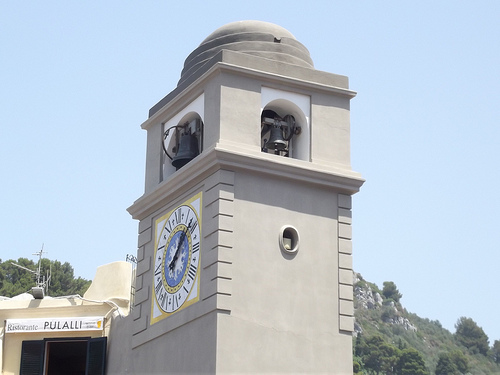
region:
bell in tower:
[267, 119, 289, 150]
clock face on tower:
[152, 201, 197, 315]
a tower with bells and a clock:
[128, 17, 365, 372]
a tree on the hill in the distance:
[452, 317, 490, 349]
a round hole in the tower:
[276, 222, 301, 257]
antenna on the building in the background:
[12, 246, 60, 293]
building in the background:
[1, 258, 132, 373]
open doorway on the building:
[44, 339, 88, 374]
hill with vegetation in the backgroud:
[352, 264, 497, 374]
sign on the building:
[4, 319, 104, 331]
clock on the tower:
[148, 212, 202, 312]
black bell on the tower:
[256, 100, 304, 162]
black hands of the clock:
[173, 216, 185, 259]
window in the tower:
[275, 219, 307, 259]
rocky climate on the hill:
[359, 277, 384, 316]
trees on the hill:
[358, 330, 423, 372]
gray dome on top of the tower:
[170, 21, 327, 59]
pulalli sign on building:
[40, 318, 81, 331]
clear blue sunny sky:
[25, 65, 102, 142]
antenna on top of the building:
[10, 239, 53, 286]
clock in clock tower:
[157, 212, 197, 316]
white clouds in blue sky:
[8, 13, 58, 59]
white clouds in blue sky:
[7, 70, 90, 144]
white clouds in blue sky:
[13, 143, 87, 193]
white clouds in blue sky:
[9, 164, 90, 223]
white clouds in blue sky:
[69, 18, 143, 77]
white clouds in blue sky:
[304, 3, 392, 39]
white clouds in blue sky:
[386, 20, 450, 83]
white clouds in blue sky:
[361, 60, 444, 117]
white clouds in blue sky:
[382, 128, 456, 205]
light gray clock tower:
[104, 25, 359, 374]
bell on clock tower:
[151, 109, 302, 161]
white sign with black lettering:
[7, 318, 103, 332]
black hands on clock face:
[161, 232, 189, 267]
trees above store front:
[0, 251, 94, 298]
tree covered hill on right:
[353, 275, 495, 366]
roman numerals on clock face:
[147, 203, 202, 303]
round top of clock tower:
[183, 23, 303, 67]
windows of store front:
[22, 340, 105, 372]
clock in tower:
[155, 203, 210, 305]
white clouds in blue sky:
[39, 197, 98, 245]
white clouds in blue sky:
[77, 126, 140, 180]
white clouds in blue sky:
[100, 53, 155, 93]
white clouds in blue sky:
[326, 10, 401, 69]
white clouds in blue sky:
[435, 69, 483, 102]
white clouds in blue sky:
[390, 118, 499, 203]